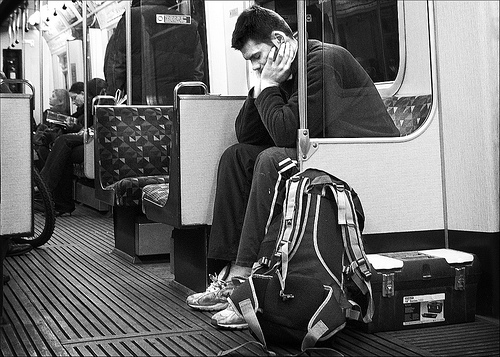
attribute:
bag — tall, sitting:
[269, 173, 367, 339]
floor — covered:
[138, 324, 195, 356]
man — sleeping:
[227, 20, 344, 231]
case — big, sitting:
[374, 236, 478, 328]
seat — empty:
[111, 96, 188, 205]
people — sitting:
[33, 73, 113, 147]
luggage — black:
[267, 181, 471, 328]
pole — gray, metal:
[293, 9, 308, 46]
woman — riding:
[45, 86, 70, 125]